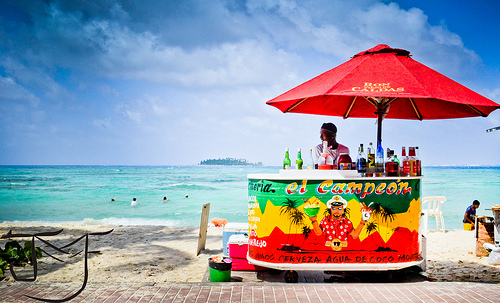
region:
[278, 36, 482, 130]
A red umbrella at a beach bar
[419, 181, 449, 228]
A white plastic chair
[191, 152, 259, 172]
An island in the distance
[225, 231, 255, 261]
A red and white cooler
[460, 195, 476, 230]
A man in a blue shirt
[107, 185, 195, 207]
Swimmers in the water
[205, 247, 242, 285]
A green trash can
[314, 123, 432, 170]
Bottles lined up on the bar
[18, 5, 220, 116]
A beautiful blue cloudy sky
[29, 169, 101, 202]
Brilliant blue water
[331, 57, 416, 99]
The logo of the umbrella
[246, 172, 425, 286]
The stand's company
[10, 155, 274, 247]
Tropical water here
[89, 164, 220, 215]
People are swimming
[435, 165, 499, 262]
A man is eating in the corner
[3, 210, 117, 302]
Some trees are pictured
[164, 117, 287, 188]
A rock formation in the background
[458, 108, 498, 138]
Another umbrella on the right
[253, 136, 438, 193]
Bottles on the counter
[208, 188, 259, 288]
The man's supply behind the stand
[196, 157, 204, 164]
a tree in a distance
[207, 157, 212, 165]
a tree in a distance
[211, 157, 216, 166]
a tree in a distance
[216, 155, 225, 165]
a tree in a distance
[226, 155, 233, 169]
a tree in a distance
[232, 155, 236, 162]
a tree in a distance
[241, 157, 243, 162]
a tree in a distance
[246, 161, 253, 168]
a tree in a distance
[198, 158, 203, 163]
a tree in a distance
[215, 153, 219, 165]
a tree in a distance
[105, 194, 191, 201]
four heads sticking out of the water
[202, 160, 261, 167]
island in the distance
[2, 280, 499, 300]
red brick walkway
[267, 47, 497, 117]
red umbrella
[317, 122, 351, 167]
man standing behind a beverage cart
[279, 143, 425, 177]
bottles of booze on a beverage cart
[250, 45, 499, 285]
beverage cart at the beach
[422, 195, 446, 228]
white plastic chair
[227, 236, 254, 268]
red cooler next to the beverage cart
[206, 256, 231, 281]
green trashcan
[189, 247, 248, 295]
Small green bucket with black liner.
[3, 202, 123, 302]
J.F WRITTEN IN BLACK.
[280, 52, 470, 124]
Red beach umbrella with yellow writing.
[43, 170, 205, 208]
A group of people swimming.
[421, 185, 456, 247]
White chair on the beach.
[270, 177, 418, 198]
Words that say el campeon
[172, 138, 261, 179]
Island in the water.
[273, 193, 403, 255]
Picture of man holding drinks.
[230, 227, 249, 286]
Red cooler with white lid.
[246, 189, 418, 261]
Yellow green and red picture.